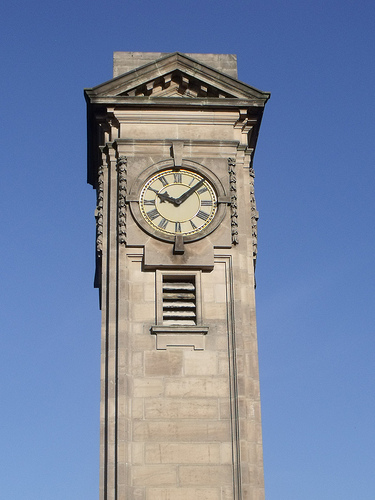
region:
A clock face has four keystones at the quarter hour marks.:
[128, 141, 232, 252]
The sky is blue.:
[0, 2, 373, 499]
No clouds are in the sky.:
[0, 0, 374, 498]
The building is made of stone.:
[83, 52, 270, 498]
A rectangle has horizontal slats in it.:
[154, 266, 202, 325]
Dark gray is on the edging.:
[85, 53, 269, 103]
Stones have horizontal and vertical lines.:
[98, 353, 270, 497]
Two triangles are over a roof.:
[107, 50, 238, 105]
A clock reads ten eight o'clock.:
[126, 159, 229, 253]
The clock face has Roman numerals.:
[141, 168, 219, 238]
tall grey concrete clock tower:
[77, 47, 274, 498]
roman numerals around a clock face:
[139, 165, 222, 238]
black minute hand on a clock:
[171, 174, 209, 207]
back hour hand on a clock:
[150, 189, 174, 205]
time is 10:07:
[136, 165, 221, 237]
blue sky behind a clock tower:
[2, 2, 373, 494]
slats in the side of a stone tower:
[156, 272, 201, 330]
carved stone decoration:
[224, 152, 241, 246]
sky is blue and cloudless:
[2, 4, 373, 498]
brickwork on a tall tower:
[101, 111, 263, 499]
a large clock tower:
[86, 40, 275, 496]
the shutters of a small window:
[150, 258, 204, 357]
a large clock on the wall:
[130, 163, 219, 242]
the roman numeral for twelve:
[170, 167, 186, 187]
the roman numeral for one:
[183, 167, 197, 188]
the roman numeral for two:
[195, 186, 211, 198]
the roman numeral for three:
[196, 196, 216, 206]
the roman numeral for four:
[193, 205, 210, 221]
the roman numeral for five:
[183, 215, 199, 230]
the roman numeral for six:
[169, 218, 186, 235]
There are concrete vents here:
[171, 284, 189, 363]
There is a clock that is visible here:
[156, 155, 213, 272]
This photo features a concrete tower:
[71, 111, 337, 466]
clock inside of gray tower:
[134, 145, 220, 251]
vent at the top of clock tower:
[147, 264, 195, 340]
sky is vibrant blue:
[298, 429, 329, 454]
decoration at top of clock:
[94, 59, 226, 119]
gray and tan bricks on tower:
[186, 445, 216, 472]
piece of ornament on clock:
[164, 142, 196, 173]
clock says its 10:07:
[141, 168, 212, 232]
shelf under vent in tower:
[149, 328, 226, 354]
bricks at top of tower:
[112, 47, 260, 86]